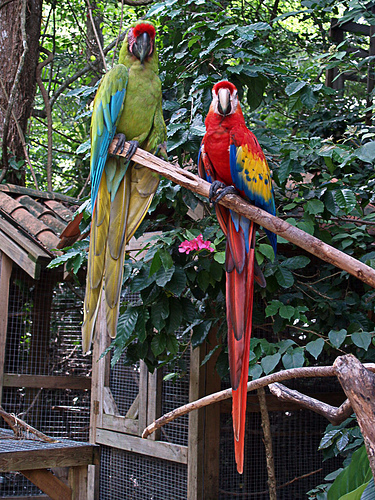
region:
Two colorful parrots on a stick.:
[80, 19, 277, 474]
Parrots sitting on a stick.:
[78, 21, 374, 474]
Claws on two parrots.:
[90, 130, 237, 205]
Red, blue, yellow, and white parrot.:
[196, 77, 278, 473]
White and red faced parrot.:
[205, 76, 241, 113]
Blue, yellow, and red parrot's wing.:
[227, 131, 285, 251]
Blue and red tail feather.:
[222, 240, 252, 474]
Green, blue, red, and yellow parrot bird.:
[76, 17, 166, 355]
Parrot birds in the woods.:
[77, 18, 277, 472]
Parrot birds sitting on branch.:
[79, 20, 280, 474]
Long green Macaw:
[84, 12, 165, 359]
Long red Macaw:
[182, 69, 277, 478]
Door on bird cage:
[81, 357, 202, 497]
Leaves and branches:
[255, 321, 369, 491]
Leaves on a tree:
[167, 3, 366, 74]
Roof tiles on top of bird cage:
[0, 191, 75, 252]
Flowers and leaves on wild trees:
[166, 229, 217, 319]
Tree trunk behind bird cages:
[7, 5, 38, 185]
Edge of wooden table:
[1, 393, 114, 498]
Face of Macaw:
[207, 80, 241, 119]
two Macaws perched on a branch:
[62, 19, 295, 475]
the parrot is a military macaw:
[76, 18, 166, 353]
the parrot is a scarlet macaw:
[190, 76, 276, 474]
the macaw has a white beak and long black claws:
[206, 77, 239, 208]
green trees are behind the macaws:
[0, 0, 369, 271]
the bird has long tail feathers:
[216, 210, 247, 474]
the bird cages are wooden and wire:
[0, 177, 367, 485]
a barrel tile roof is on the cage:
[0, 180, 92, 496]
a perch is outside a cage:
[2, 420, 95, 497]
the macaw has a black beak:
[116, 15, 161, 84]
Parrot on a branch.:
[180, 93, 296, 162]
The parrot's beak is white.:
[211, 95, 236, 110]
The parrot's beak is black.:
[128, 34, 169, 53]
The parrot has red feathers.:
[206, 120, 239, 145]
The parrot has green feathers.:
[134, 90, 152, 118]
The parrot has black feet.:
[200, 180, 242, 198]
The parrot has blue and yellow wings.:
[236, 171, 272, 199]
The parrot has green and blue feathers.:
[80, 102, 131, 129]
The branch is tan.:
[137, 152, 160, 173]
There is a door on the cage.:
[108, 465, 141, 488]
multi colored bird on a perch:
[191, 76, 282, 376]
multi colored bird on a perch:
[76, 8, 170, 350]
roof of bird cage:
[2, 175, 92, 269]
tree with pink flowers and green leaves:
[157, 235, 223, 265]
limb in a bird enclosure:
[131, 306, 330, 432]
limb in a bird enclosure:
[311, 352, 373, 465]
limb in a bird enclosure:
[1, 398, 65, 450]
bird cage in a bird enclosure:
[8, 277, 85, 421]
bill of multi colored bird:
[178, 76, 272, 139]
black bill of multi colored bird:
[130, 26, 159, 66]